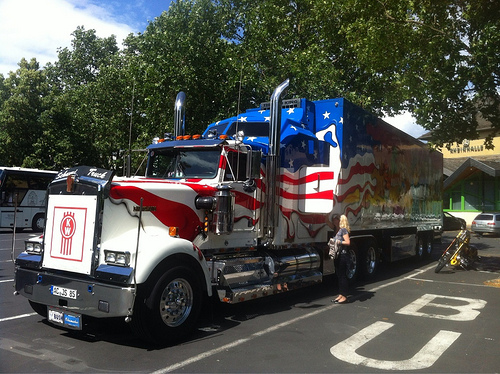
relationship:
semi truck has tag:
[12, 76, 442, 346] [50, 283, 77, 300]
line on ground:
[206, 315, 285, 354] [247, 316, 497, 371]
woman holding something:
[328, 208, 352, 307] [322, 237, 342, 259]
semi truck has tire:
[12, 76, 442, 346] [145, 262, 215, 341]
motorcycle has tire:
[434, 213, 483, 273] [434, 255, 452, 273]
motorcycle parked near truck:
[434, 213, 483, 273] [42, 112, 447, 332]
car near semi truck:
[468, 207, 498, 232] [12, 76, 442, 346]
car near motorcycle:
[468, 207, 498, 232] [433, 215, 476, 290]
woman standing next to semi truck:
[328, 208, 352, 307] [12, 76, 442, 346]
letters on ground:
[327, 292, 488, 374] [4, 226, 495, 368]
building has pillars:
[440, 155, 498, 231] [447, 184, 464, 212]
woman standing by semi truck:
[328, 208, 352, 307] [12, 76, 442, 346]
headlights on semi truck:
[23, 238, 133, 273] [12, 76, 442, 346]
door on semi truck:
[220, 137, 261, 234] [12, 76, 442, 346]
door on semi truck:
[220, 145, 257, 241] [12, 76, 442, 346]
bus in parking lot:
[2, 149, 79, 235] [2, 225, 483, 371]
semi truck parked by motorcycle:
[12, 76, 442, 346] [433, 223, 483, 275]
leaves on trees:
[2, 0, 484, 157] [222, 5, 483, 153]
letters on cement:
[331, 287, 488, 371] [167, 259, 484, 372]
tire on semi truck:
[130, 253, 210, 353] [12, 76, 442, 346]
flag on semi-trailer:
[49, 205, 90, 264] [209, 91, 455, 259]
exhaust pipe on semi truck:
[261, 79, 292, 243] [12, 76, 442, 346]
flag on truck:
[49, 205, 90, 264] [12, 79, 447, 333]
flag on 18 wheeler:
[108, 97, 383, 259] [10, 75, 445, 341]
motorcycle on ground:
[432, 222, 479, 276] [433, 137, 447, 143]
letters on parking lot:
[327, 292, 488, 374] [165, 251, 497, 372]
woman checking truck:
[328, 208, 352, 307] [55, 80, 474, 340]